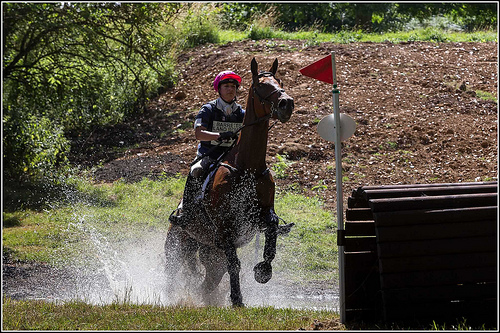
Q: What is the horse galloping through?
A: Water.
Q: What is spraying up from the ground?
A: Water.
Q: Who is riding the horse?
A: A jockey.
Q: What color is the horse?
A: Brown.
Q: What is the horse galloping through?
A: Water.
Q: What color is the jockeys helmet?
A: Red.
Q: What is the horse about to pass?
A: A flag.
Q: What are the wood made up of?
A: Green trees.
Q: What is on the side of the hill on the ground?
A: Dirt.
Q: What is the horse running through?
A: Water.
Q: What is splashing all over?
A: Water.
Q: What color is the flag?
A: Red.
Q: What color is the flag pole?
A: Silver.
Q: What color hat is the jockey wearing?
A: Red.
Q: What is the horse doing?
A: Running.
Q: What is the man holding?
A: Reins.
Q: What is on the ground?
A: Dirt.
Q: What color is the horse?
A: Brown.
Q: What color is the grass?
A: Green.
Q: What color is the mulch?
A: Brown.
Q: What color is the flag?
A: Red.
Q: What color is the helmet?
A: Red.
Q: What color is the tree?
A: Brown.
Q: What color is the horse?
A: Brown.